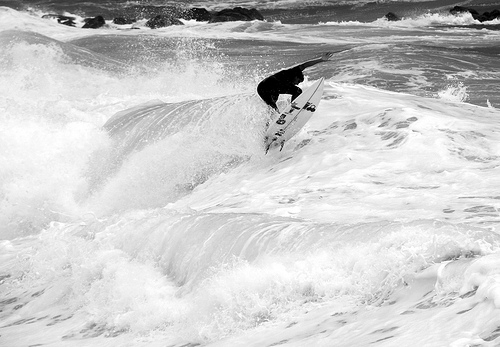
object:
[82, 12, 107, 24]
rock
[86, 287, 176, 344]
wave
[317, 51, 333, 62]
hand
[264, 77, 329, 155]
surfboard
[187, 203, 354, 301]
wave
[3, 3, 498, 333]
ocean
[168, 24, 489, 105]
spot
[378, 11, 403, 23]
rock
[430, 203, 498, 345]
water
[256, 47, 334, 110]
man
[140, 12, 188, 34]
rocks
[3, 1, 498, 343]
photo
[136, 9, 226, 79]
water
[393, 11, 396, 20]
air